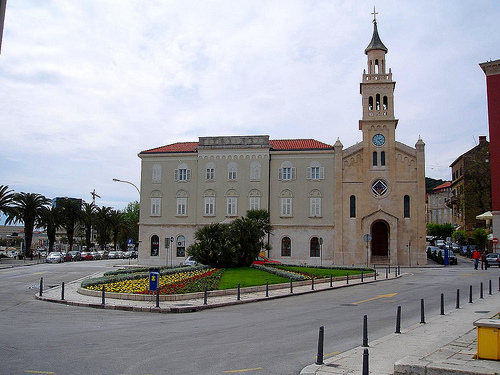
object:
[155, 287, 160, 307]
post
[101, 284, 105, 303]
post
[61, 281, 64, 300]
post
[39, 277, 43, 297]
post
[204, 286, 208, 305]
post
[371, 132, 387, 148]
clock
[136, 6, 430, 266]
building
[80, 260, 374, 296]
flower bed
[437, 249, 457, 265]
car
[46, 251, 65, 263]
car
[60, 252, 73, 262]
car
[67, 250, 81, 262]
car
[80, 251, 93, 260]
car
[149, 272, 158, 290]
sign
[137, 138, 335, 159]
roof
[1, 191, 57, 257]
tree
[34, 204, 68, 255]
tree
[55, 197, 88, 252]
tree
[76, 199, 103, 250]
tree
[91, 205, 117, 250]
tree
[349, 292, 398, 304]
arrow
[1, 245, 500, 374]
street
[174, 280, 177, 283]
flowers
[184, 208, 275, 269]
bush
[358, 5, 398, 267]
tower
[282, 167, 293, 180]
window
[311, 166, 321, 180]
window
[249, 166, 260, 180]
window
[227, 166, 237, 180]
window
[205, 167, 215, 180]
window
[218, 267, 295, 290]
grass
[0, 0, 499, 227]
sky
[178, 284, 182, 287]
flowers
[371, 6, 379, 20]
cross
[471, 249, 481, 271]
man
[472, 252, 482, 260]
shirt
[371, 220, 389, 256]
door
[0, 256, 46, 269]
sidewalk